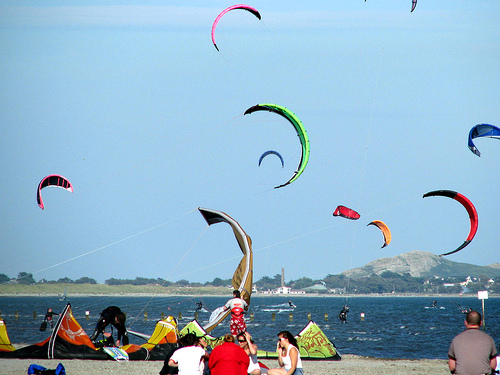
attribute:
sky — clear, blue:
[2, 4, 495, 243]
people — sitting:
[90, 311, 497, 375]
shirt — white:
[166, 345, 208, 374]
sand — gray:
[310, 359, 441, 374]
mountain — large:
[300, 247, 499, 298]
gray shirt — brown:
[443, 324, 499, 375]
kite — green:
[238, 96, 315, 191]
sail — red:
[330, 196, 360, 226]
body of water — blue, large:
[3, 293, 494, 318]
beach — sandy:
[68, 359, 155, 371]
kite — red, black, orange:
[419, 184, 482, 258]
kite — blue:
[466, 119, 499, 156]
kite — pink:
[207, 2, 264, 54]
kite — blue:
[254, 145, 286, 173]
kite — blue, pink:
[34, 172, 74, 212]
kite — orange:
[368, 217, 392, 248]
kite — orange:
[23, 298, 98, 363]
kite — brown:
[193, 202, 257, 294]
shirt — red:
[204, 332, 254, 374]